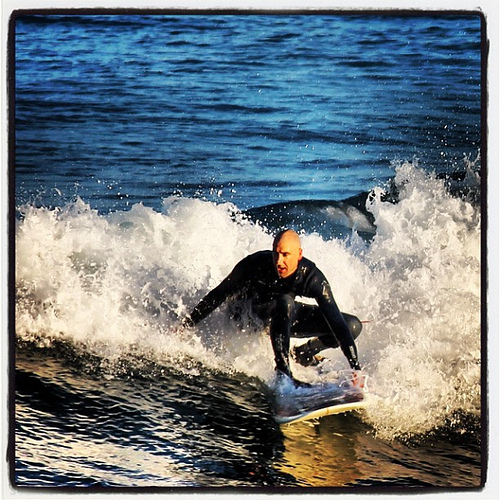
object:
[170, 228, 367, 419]
man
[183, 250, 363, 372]
wet suit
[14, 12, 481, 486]
water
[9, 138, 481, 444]
wave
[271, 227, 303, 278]
head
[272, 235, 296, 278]
face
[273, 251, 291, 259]
eyes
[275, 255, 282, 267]
nose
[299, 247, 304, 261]
ear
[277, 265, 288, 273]
mouth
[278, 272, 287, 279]
chin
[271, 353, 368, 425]
surfboard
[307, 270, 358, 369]
arm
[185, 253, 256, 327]
arm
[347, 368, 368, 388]
hand